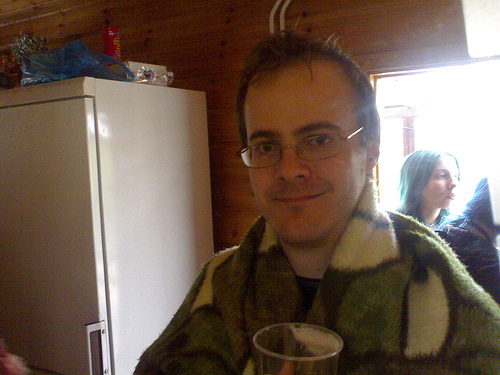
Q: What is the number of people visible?
A: Three.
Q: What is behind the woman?
A: A window.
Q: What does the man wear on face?
A: Glasses.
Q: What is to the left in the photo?
A: A refrigerator.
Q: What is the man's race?
A: Caucasian.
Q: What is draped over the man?
A: A blanket.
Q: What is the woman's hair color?
A: Brown.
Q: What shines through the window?
A: Sunlight.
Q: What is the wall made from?
A: Wood.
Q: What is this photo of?
A: A room.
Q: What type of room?
A: A kitchen.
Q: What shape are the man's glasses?
A: Oval.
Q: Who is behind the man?
A: A woman.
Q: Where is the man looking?
A: At the camera.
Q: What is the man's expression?
A: A smile.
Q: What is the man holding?
A: A cup.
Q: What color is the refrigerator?
A: White.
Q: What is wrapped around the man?
A: A blanket.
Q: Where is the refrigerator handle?
A: On the door.